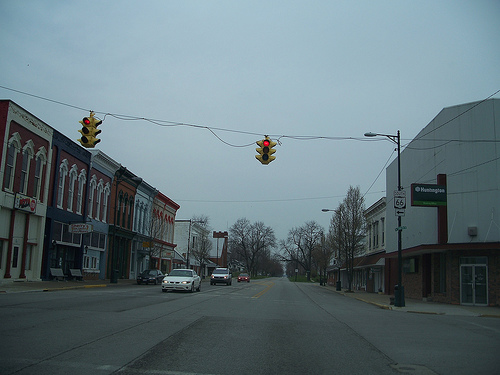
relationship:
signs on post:
[391, 190, 410, 234] [396, 129, 405, 308]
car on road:
[137, 268, 168, 288] [0, 275, 500, 374]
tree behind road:
[226, 216, 278, 280] [0, 275, 500, 374]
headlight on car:
[163, 279, 190, 288] [163, 268, 201, 294]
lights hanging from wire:
[76, 111, 278, 166] [154, 103, 373, 147]